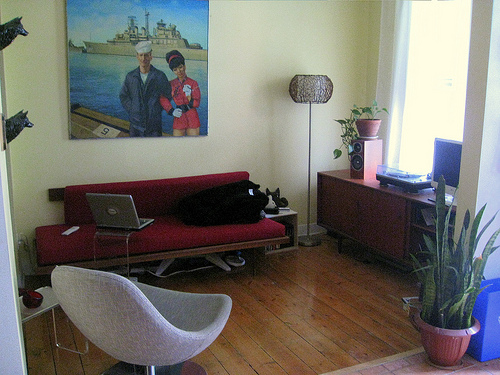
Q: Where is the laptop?
A: On small table near couch.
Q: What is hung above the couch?
A: Art work.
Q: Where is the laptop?
A: On the couch.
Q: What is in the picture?
A: A man, a woman and a boat.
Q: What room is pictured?
A: Small living room.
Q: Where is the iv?
A: In a pot near the window.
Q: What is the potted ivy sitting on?
A: Speaker.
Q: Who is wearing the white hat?
A: Sailor in the painting.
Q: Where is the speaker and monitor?
A: On top of the credenza.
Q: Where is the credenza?
A: In front of the window.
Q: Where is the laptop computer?
A: In front of the couch.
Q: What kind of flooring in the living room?
A: Wood plank.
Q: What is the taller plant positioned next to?
A: Door frame.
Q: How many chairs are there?
A: One.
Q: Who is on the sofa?
A: No one.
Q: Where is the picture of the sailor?
A: On the wall.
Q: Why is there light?
A: The window is open.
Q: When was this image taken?
A: Daytime.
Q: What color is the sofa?
A: Red.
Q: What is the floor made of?
A: Wood.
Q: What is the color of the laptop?
A: Gray.